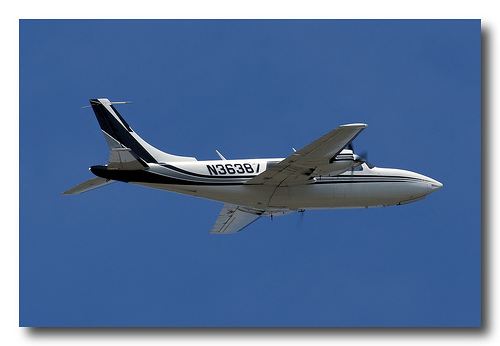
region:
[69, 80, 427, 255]
Small plane in the sky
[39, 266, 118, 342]
Small patch of blue sky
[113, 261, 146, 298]
Small patch of blue sky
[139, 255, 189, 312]
Small patch of blue sky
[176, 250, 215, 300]
Small patch of blue sky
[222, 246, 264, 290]
Small patch of blue sky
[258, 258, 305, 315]
Small patch of blue sky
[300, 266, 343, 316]
Small patch of blue sky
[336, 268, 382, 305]
Small patch of blue sky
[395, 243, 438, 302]
Small patch of blue sky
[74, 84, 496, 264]
SMALL WHITE PLANE IN MID AIR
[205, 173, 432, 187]
BLACK STRIPES ON PLANE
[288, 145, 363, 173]
SMALL PROPELLER ENGINE ON WING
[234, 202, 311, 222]
SMALL PROPELLER ENGINE ON WING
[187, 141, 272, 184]
IDENTIFICATION NUMBER ON PLANE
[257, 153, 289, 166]
SMALL WINDOW OVER WING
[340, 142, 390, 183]
glass windows in cockpit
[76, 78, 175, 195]
black stripe on tail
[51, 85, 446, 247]
Airplane in the sky.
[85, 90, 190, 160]
Blue, gray, and white colors on the tail.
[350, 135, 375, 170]
Propeller on the plane.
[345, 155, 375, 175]
Windows on the plane.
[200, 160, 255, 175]
Numbers on the plane.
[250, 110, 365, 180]
Wing on the plane.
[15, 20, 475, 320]
blue sky in the background.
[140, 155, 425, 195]
Blue and gray stripe on the plane.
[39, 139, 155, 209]
Back wings on the plane.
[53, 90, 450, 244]
a plane is color white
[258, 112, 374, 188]
right wing of plane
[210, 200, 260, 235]
left wing of plane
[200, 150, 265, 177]
number of plane N36387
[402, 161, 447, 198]
the cockpit of plane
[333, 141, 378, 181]
the engine of plane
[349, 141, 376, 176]
the propeller of plane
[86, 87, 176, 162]
vertical stabilizer of plane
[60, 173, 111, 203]
horizontal on side the plane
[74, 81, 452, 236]
plane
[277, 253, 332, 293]
white clouds in blue sky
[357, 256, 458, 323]
white clouds in blue sky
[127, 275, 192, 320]
white clouds in blue sky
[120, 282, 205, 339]
white clouds in blue sky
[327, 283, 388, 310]
white clouds in blue sky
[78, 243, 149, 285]
white clouds in blue sky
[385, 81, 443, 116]
white clouds in blue sky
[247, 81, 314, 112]
white clouds in blue sky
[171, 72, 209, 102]
white clouds in blue sky